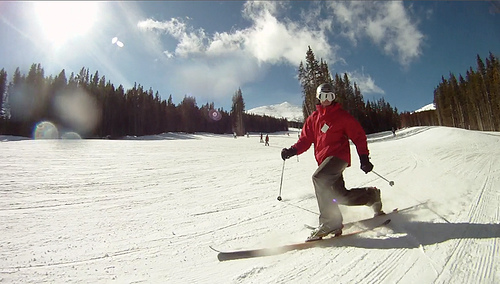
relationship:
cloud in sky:
[137, 0, 433, 95] [2, 3, 483, 113]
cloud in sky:
[137, 0, 433, 95] [1, 0, 492, 54]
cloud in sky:
[137, 0, 433, 95] [5, 7, 494, 119]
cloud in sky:
[319, 5, 434, 68] [5, 7, 494, 119]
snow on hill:
[2, 128, 482, 278] [6, 106, 483, 275]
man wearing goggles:
[277, 76, 386, 246] [311, 79, 343, 102]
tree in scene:
[224, 82, 249, 140] [3, 1, 482, 281]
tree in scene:
[123, 79, 157, 138] [3, 1, 482, 281]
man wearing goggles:
[281, 83, 382, 242] [317, 92, 335, 102]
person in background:
[230, 128, 237, 139] [2, 3, 484, 153]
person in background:
[245, 128, 250, 139] [2, 3, 484, 153]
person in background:
[257, 130, 264, 144] [2, 3, 484, 153]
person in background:
[262, 130, 270, 146] [2, 3, 484, 153]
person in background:
[387, 126, 399, 137] [2, 3, 484, 153]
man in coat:
[281, 83, 382, 242] [291, 100, 369, 166]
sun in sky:
[21, 0, 117, 65] [130, 13, 248, 87]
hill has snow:
[245, 101, 305, 122] [2, 128, 482, 278]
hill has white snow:
[245, 101, 305, 122] [53, 147, 255, 215]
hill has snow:
[245, 101, 305, 122] [114, 169, 192, 226]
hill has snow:
[245, 101, 305, 122] [35, 156, 236, 247]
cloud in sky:
[137, 0, 433, 95] [7, 4, 495, 139]